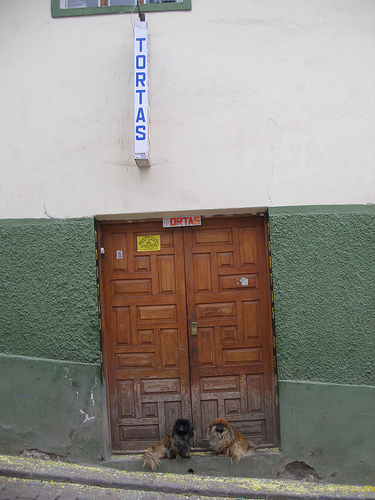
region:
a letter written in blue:
[132, 32, 145, 51]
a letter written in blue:
[133, 50, 147, 69]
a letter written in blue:
[132, 68, 148, 87]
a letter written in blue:
[135, 88, 148, 106]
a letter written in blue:
[133, 102, 146, 123]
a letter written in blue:
[133, 123, 146, 141]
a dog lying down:
[137, 411, 195, 471]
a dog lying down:
[204, 413, 251, 461]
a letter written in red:
[166, 213, 179, 230]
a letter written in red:
[190, 211, 200, 226]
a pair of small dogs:
[139, 416, 255, 466]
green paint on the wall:
[0, 203, 374, 483]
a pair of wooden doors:
[94, 208, 278, 453]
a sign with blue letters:
[132, 22, 148, 165]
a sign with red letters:
[162, 215, 201, 228]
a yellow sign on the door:
[137, 235, 159, 250]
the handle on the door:
[190, 321, 197, 334]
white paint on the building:
[0, 0, 372, 218]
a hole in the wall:
[286, 460, 319, 478]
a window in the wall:
[50, 0, 191, 18]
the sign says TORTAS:
[132, 25, 147, 153]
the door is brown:
[86, 203, 280, 459]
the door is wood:
[90, 206, 279, 461]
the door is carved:
[87, 214, 281, 463]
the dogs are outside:
[141, 412, 252, 489]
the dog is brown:
[204, 411, 260, 466]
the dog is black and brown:
[132, 416, 199, 481]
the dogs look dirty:
[136, 414, 257, 494]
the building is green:
[0, 203, 373, 498]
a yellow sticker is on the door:
[130, 230, 166, 260]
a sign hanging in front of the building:
[132, 23, 151, 171]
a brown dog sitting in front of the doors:
[205, 414, 248, 459]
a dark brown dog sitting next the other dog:
[136, 416, 193, 472]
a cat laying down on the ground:
[276, 456, 322, 486]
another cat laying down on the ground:
[21, 447, 74, 464]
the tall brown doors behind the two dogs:
[99, 219, 284, 456]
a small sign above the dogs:
[157, 220, 205, 228]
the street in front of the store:
[1, 477, 180, 498]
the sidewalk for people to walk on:
[2, 451, 356, 499]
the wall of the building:
[4, 192, 366, 470]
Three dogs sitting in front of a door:
[127, 394, 273, 481]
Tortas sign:
[89, 5, 188, 191]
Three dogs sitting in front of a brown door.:
[83, 207, 309, 484]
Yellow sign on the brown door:
[118, 219, 180, 269]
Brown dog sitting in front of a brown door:
[196, 416, 265, 467]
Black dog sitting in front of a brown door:
[158, 409, 201, 461]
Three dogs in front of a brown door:
[99, 404, 284, 477]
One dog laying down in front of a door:
[131, 412, 266, 479]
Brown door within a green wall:
[23, 204, 343, 477]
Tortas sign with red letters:
[148, 209, 215, 233]